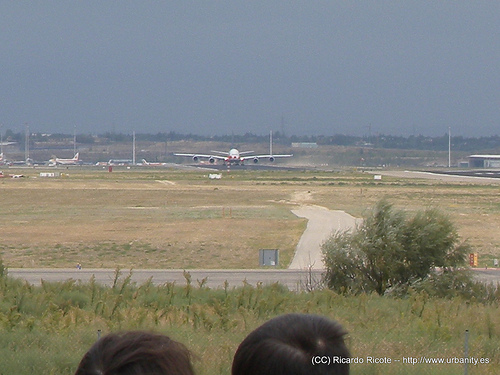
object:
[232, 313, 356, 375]
hair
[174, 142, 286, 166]
plane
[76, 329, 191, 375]
man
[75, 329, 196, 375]
hair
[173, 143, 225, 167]
wing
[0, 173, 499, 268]
field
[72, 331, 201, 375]
head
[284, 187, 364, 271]
road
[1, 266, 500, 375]
weeds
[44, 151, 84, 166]
airplane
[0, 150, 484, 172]
airport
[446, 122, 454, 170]
post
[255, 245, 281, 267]
box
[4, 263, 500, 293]
road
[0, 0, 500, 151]
skyline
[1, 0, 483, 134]
sky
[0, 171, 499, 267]
desert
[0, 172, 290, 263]
ground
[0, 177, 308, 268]
grass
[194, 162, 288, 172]
dirt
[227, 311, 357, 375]
people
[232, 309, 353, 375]
heads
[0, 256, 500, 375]
grass